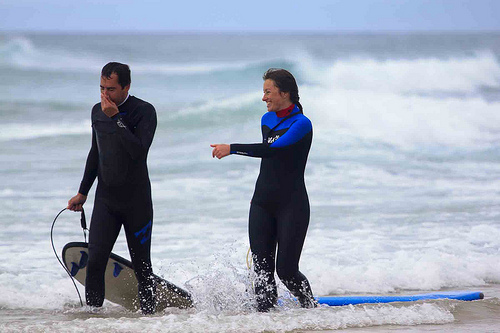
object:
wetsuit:
[232, 104, 317, 313]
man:
[65, 60, 158, 316]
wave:
[0, 83, 499, 165]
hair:
[100, 60, 132, 89]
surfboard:
[279, 292, 487, 307]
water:
[0, 26, 499, 332]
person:
[207, 65, 319, 313]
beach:
[0, 279, 499, 332]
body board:
[61, 240, 195, 312]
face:
[260, 78, 282, 114]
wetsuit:
[76, 94, 160, 317]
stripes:
[131, 220, 153, 238]